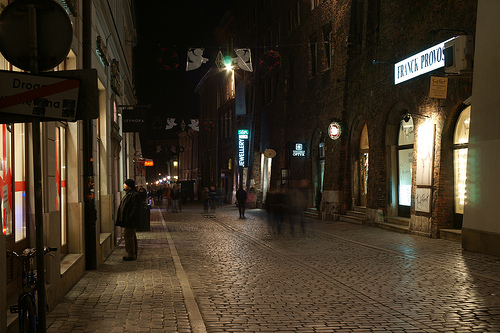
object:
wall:
[238, 0, 500, 268]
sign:
[0, 68, 82, 124]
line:
[0, 79, 79, 109]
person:
[116, 179, 151, 261]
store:
[0, 0, 81, 312]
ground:
[0, 206, 500, 333]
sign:
[392, 36, 455, 86]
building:
[271, 0, 481, 244]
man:
[114, 178, 143, 260]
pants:
[123, 228, 139, 257]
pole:
[83, 2, 96, 273]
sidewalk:
[2, 208, 208, 333]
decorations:
[186, 46, 253, 73]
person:
[114, 178, 143, 261]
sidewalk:
[40, 209, 208, 333]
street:
[0, 202, 500, 333]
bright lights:
[156, 176, 179, 185]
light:
[225, 64, 233, 71]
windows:
[359, 123, 370, 195]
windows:
[396, 114, 414, 207]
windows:
[453, 105, 475, 214]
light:
[224, 65, 232, 71]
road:
[0, 206, 500, 333]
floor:
[23, 207, 498, 333]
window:
[97, 143, 108, 193]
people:
[264, 185, 285, 235]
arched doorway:
[394, 117, 413, 218]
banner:
[233, 48, 253, 72]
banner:
[186, 46, 208, 71]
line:
[125, 39, 330, 47]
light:
[418, 119, 434, 163]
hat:
[123, 179, 135, 188]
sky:
[134, 0, 189, 114]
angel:
[186, 48, 209, 72]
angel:
[232, 50, 254, 73]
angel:
[166, 118, 177, 130]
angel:
[188, 119, 200, 131]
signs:
[238, 129, 249, 135]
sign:
[1, 0, 93, 333]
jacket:
[113, 191, 143, 228]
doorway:
[379, 107, 415, 234]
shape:
[387, 104, 416, 228]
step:
[339, 215, 363, 225]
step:
[346, 210, 367, 218]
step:
[354, 205, 366, 212]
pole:
[28, 120, 48, 330]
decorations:
[230, 48, 252, 73]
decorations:
[165, 118, 178, 129]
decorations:
[188, 119, 200, 132]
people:
[287, 180, 314, 235]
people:
[114, 179, 147, 262]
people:
[235, 187, 248, 218]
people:
[201, 187, 209, 214]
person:
[236, 188, 248, 219]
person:
[286, 178, 313, 236]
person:
[259, 187, 286, 235]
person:
[209, 186, 218, 213]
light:
[327, 121, 342, 141]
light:
[173, 161, 178, 168]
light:
[224, 56, 235, 73]